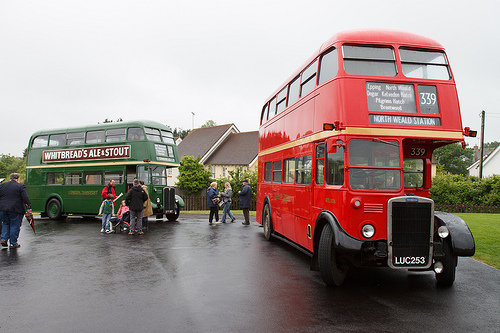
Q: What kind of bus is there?
A: Double decker.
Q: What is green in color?
A: A double decker bus.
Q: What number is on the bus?
A: 339.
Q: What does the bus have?
A: Windows.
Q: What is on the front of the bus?
A: Lights.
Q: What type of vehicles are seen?
A: Buses.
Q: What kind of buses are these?
A: Double decker.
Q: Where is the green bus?
A: Parked next to a house.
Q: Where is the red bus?
A: In front of the green bus.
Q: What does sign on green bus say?
A: Whitbread's ale & stout.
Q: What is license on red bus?
A: Luc253.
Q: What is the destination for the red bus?
A: North weald station.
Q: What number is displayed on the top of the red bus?
A: 339.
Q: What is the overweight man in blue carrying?
A: Umbrella.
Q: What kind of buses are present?
A: Double decker.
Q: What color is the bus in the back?
A: Green.